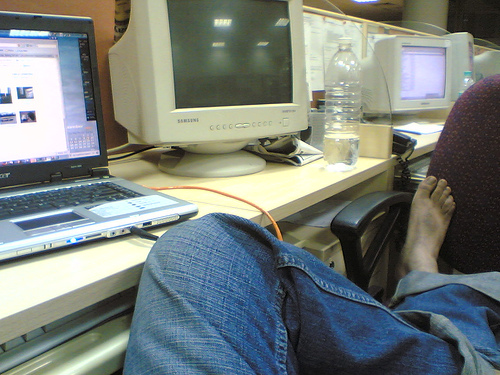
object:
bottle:
[458, 70, 477, 98]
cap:
[464, 70, 473, 76]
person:
[125, 176, 500, 375]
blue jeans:
[123, 212, 499, 374]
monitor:
[401, 45, 450, 100]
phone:
[392, 129, 418, 185]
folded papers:
[242, 134, 324, 166]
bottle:
[322, 37, 364, 173]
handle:
[329, 190, 414, 306]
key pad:
[0, 181, 147, 221]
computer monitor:
[165, 0, 293, 109]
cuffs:
[387, 270, 500, 375]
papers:
[302, 14, 363, 92]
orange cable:
[142, 185, 283, 242]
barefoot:
[396, 175, 456, 284]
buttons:
[209, 121, 272, 130]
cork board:
[310, 90, 325, 111]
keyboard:
[0, 283, 142, 374]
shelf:
[0, 155, 403, 374]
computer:
[108, 0, 308, 178]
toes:
[419, 175, 457, 218]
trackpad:
[14, 212, 84, 231]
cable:
[130, 185, 283, 241]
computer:
[0, 9, 198, 265]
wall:
[0, 0, 391, 156]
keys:
[0, 182, 146, 220]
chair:
[331, 73, 500, 304]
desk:
[0, 123, 392, 375]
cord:
[392, 147, 412, 191]